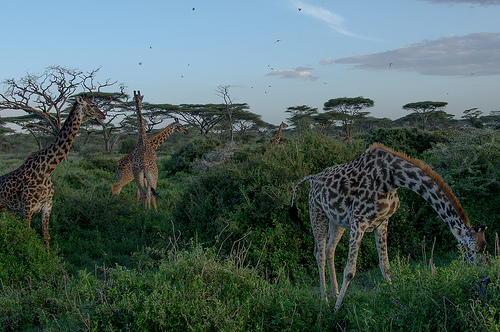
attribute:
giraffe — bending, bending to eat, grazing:
[288, 139, 488, 314]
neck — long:
[401, 151, 474, 225]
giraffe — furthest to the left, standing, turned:
[110, 117, 189, 193]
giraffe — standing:
[131, 88, 161, 211]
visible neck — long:
[45, 122, 82, 167]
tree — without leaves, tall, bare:
[1, 63, 128, 159]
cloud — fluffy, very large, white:
[319, 32, 499, 75]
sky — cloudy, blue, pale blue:
[1, 2, 499, 82]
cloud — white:
[260, 64, 324, 92]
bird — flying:
[273, 37, 286, 48]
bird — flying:
[295, 4, 306, 17]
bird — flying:
[188, 5, 198, 13]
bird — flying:
[137, 60, 146, 69]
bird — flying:
[147, 42, 160, 51]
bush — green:
[1, 214, 89, 329]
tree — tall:
[323, 96, 375, 136]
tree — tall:
[403, 98, 448, 131]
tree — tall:
[185, 103, 249, 135]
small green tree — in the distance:
[459, 106, 485, 125]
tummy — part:
[321, 188, 351, 229]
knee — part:
[342, 268, 358, 284]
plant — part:
[138, 224, 289, 332]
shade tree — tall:
[281, 105, 321, 132]